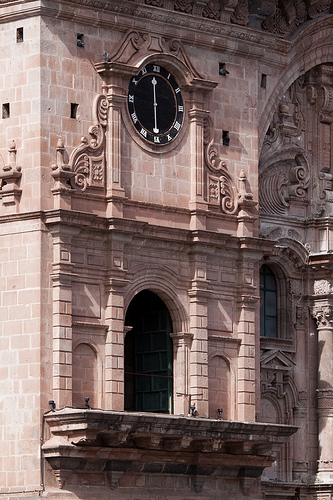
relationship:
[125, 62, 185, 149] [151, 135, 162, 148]
clock shows six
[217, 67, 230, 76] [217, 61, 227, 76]
bird in hole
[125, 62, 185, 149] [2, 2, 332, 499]
clock on side of building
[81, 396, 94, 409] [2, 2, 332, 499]
spotlight on side of building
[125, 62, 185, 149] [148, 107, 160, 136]
clock has hand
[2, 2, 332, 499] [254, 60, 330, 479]
building has arch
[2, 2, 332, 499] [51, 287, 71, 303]
building has brick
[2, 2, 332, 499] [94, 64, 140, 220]
building has column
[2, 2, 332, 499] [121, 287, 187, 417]
building has window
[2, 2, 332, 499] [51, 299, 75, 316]
building has brick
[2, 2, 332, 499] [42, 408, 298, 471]
building has balcony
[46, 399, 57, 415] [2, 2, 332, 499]
light on building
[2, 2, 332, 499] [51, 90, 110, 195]
building has carving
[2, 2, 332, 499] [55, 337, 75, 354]
building has brick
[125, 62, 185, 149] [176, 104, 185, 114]
clock has number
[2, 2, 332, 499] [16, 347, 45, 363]
building has brick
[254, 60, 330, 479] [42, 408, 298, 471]
arch near balcony